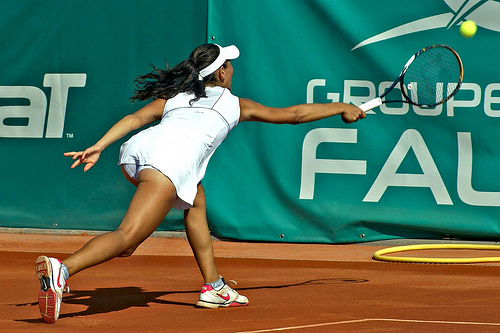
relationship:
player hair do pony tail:
[32, 41, 366, 323] [130, 46, 228, 106]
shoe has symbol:
[196, 281, 249, 309] [216, 293, 230, 303]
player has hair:
[32, 41, 366, 323] [129, 41, 228, 106]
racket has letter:
[360, 44, 465, 113] [420, 53, 453, 94]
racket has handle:
[360, 44, 465, 113] [358, 98, 382, 114]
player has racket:
[32, 41, 366, 323] [360, 44, 465, 113]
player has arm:
[32, 41, 366, 323] [239, 96, 368, 125]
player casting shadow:
[32, 39, 366, 327] [11, 274, 367, 331]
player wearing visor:
[32, 41, 366, 323] [194, 43, 240, 80]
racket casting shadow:
[360, 44, 465, 113] [270, 274, 371, 290]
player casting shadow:
[32, 39, 366, 327] [2, 280, 368, 325]